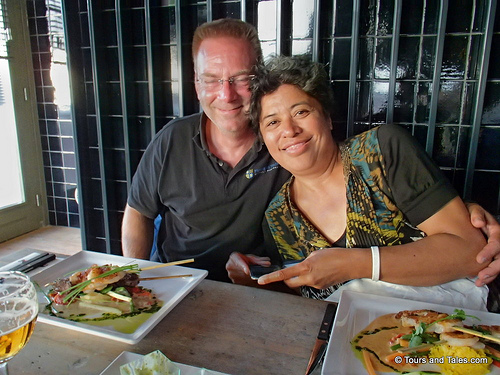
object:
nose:
[282, 118, 298, 138]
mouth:
[275, 136, 315, 159]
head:
[248, 59, 338, 178]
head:
[193, 14, 259, 139]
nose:
[218, 78, 232, 108]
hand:
[465, 201, 499, 289]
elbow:
[456, 225, 496, 283]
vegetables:
[52, 257, 156, 322]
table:
[226, 294, 316, 373]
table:
[200, 304, 298, 356]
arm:
[390, 148, 490, 275]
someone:
[222, 58, 490, 305]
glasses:
[192, 70, 259, 95]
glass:
[0, 264, 39, 374]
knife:
[307, 299, 345, 372]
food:
[351, 303, 500, 375]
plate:
[310, 286, 499, 375]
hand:
[221, 250, 273, 290]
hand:
[256, 246, 372, 292]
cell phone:
[244, 253, 283, 282]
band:
[368, 243, 382, 282]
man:
[115, 16, 498, 289]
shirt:
[122, 110, 291, 275]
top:
[252, 124, 488, 296]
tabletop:
[223, 344, 329, 371]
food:
[47, 255, 163, 325]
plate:
[0, 245, 213, 344]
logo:
[244, 166, 254, 179]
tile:
[27, 4, 78, 227]